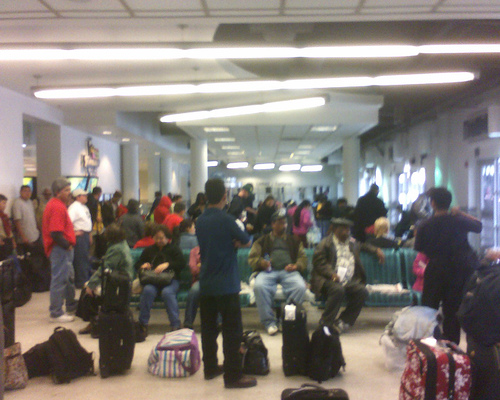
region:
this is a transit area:
[47, 22, 443, 374]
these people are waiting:
[60, 167, 375, 352]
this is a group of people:
[70, 150, 352, 310]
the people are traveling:
[65, 170, 285, 360]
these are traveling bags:
[140, 318, 207, 384]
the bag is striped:
[140, 326, 206, 374]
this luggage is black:
[93, 288, 158, 395]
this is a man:
[185, 195, 235, 316]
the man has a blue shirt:
[198, 210, 255, 303]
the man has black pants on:
[196, 286, 245, 371]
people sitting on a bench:
[93, 211, 410, 326]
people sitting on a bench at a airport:
[68, 189, 415, 346]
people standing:
[16, 155, 226, 267]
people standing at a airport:
[18, 163, 193, 303]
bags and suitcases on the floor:
[18, 294, 497, 396]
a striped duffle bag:
[143, 290, 218, 391]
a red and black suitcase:
[378, 322, 498, 398]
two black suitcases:
[265, 291, 362, 385]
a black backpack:
[32, 325, 110, 389]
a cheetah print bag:
[0, 324, 52, 391]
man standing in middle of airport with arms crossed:
[187, 173, 254, 390]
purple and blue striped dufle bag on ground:
[145, 324, 205, 384]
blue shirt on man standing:
[187, 208, 252, 300]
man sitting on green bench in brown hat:
[304, 210, 391, 333]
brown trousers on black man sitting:
[317, 277, 368, 328]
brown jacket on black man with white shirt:
[310, 232, 382, 292]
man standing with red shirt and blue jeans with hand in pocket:
[33, 176, 88, 328]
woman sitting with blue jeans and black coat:
[132, 219, 195, 345]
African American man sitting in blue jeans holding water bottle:
[244, 209, 318, 335]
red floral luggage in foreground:
[397, 333, 482, 396]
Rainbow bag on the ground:
[146, 321, 202, 385]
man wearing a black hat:
[328, 209, 357, 231]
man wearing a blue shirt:
[189, 203, 245, 299]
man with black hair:
[195, 169, 237, 214]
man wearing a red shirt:
[38, 194, 83, 249]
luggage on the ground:
[268, 283, 353, 373]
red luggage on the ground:
[403, 338, 480, 398]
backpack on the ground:
[42, 319, 99, 375]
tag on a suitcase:
[281, 298, 301, 330]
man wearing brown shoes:
[223, 366, 256, 389]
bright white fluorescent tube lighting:
[1, 37, 496, 67]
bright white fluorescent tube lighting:
[23, 70, 485, 101]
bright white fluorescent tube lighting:
[153, 92, 331, 129]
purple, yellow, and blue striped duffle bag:
[130, 316, 208, 379]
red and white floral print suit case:
[387, 337, 484, 399]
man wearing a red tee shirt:
[39, 177, 81, 328]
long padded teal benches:
[85, 232, 448, 314]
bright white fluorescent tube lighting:
[223, 157, 255, 173]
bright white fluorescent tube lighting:
[279, 155, 302, 175]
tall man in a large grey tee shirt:
[11, 182, 56, 301]